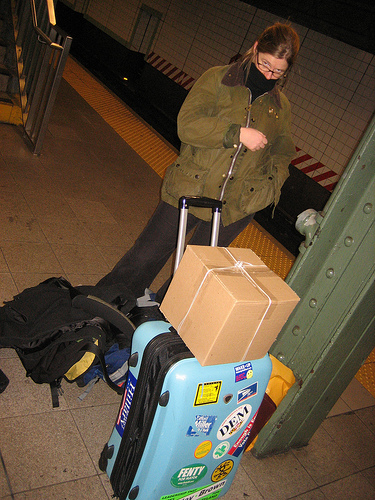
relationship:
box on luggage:
[154, 238, 302, 370] [93, 308, 275, 500]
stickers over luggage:
[214, 403, 252, 442] [93, 308, 275, 500]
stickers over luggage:
[195, 380, 221, 407] [93, 308, 275, 500]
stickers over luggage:
[235, 383, 260, 405] [93, 308, 275, 500]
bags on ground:
[2, 275, 110, 390] [1, 28, 374, 499]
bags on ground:
[73, 297, 136, 389] [1, 28, 374, 499]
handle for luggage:
[169, 192, 226, 292] [93, 308, 275, 500]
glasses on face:
[250, 51, 292, 81] [252, 48, 288, 91]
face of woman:
[252, 48, 288, 91] [82, 20, 308, 311]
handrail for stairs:
[14, 3, 76, 156] [1, 2, 25, 132]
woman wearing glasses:
[82, 20, 308, 311] [250, 51, 292, 81]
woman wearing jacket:
[82, 20, 308, 311] [155, 54, 296, 229]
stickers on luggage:
[214, 403, 252, 442] [93, 308, 275, 500]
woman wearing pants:
[82, 20, 308, 311] [82, 179, 256, 319]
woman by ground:
[82, 20, 308, 311] [1, 28, 374, 499]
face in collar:
[252, 48, 288, 91] [246, 61, 281, 93]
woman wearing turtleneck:
[82, 20, 308, 311] [239, 59, 281, 105]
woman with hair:
[82, 20, 308, 311] [235, 22, 299, 95]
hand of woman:
[237, 126, 271, 157] [82, 20, 308, 311]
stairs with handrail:
[1, 2, 25, 132] [14, 3, 76, 156]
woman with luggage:
[82, 20, 308, 311] [93, 308, 275, 500]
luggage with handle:
[93, 308, 275, 500] [169, 192, 226, 292]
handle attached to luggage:
[169, 192, 226, 292] [93, 308, 275, 500]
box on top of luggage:
[154, 238, 302, 370] [93, 308, 275, 500]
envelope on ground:
[244, 350, 297, 459] [1, 28, 374, 499]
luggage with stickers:
[93, 308, 275, 500] [214, 403, 252, 442]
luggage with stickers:
[93, 308, 275, 500] [195, 380, 221, 407]